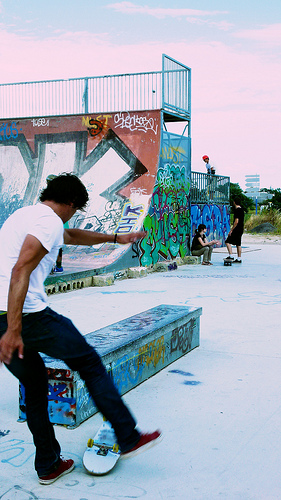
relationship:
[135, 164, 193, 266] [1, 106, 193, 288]
graffiti art on wall